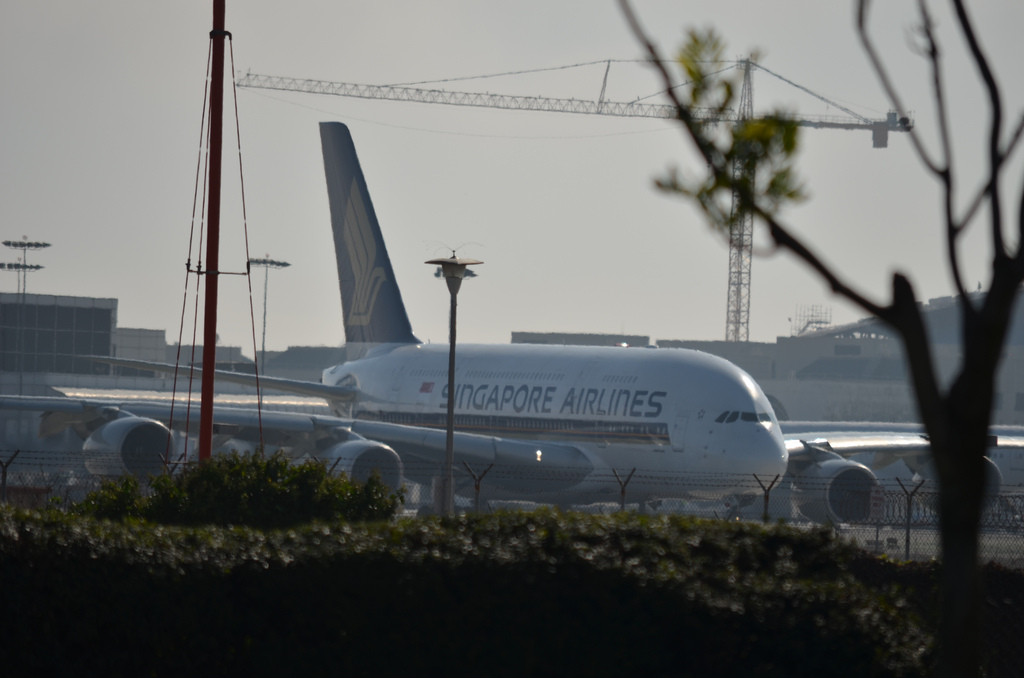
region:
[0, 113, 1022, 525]
White airplane owned by Singapore Airlines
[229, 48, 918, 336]
Tall crane in the distance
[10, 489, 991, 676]
Shrubbery in front of the runway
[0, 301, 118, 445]
Airport building next to runway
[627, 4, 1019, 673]
Top of tree in front of runway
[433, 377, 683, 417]
Company name shown on airplane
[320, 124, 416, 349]
Blue top wing on airplane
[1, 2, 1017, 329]
Gray overcast sky with no clouds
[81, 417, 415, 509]
Two jets on the right wing of a plane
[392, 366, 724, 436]
words on the side of the plane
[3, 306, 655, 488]
the wings on a plane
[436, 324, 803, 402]
the top of a plane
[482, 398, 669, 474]
the side windows on a plane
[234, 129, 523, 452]
the tale end of a plane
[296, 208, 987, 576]
a plane on a runway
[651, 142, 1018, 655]
a tree in front of a plane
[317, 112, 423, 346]
Blue and white vertical stabilizer of an airplane.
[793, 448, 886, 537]
An airplane's jet engine.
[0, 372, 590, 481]
Wing attached to an airplane fuselage.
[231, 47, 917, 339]
A large crane in front of a pale gray sky.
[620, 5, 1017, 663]
A tree with sparse green leaves.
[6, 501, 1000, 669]
A green, trimmed hedge.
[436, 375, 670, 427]
The name of a major airline.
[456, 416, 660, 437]
Small windows on the side of an airplane.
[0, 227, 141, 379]
Aerials on top of a building.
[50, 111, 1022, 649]
a large plane in the airport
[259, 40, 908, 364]
a large construction crane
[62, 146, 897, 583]
the plane says singapore airlines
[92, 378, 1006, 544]
the plane has four engines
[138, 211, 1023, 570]
the sun is cast on the plane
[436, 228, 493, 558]
a lamp post on the ground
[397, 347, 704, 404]
top of the plane is white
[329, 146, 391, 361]
tail is blue and yellow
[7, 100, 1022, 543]
large plane parked at airport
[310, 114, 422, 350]
tail of plane is black and gold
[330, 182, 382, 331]
symbol on tail of plane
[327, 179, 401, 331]
symbol on tail is gold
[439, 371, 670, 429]
airline company on side of plane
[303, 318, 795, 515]
body of plane is white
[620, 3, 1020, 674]
bare tree in front of bushes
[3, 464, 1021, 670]
row of bushes beside fence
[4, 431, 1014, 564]
fence behind bushes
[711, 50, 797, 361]
tall tower in distance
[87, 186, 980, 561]
Plane at the airport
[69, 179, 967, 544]
White plane on tarmac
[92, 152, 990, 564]
White plane at airport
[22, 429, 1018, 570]
Gate in front of plane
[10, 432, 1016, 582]
Gate in front of white plane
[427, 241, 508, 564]
Light on a pole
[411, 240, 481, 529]
Pole behind the fence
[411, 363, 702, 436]
Writing on the plane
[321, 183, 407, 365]
Logo on the plane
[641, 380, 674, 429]
letter on side of plane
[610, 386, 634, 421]
letter on side of plane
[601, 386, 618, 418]
letter on side of plane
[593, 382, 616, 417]
letter on side of plane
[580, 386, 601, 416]
letter on side of plane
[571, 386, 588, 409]
letter on side of plane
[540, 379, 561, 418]
letter on side of plane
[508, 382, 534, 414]
letter on side of plane